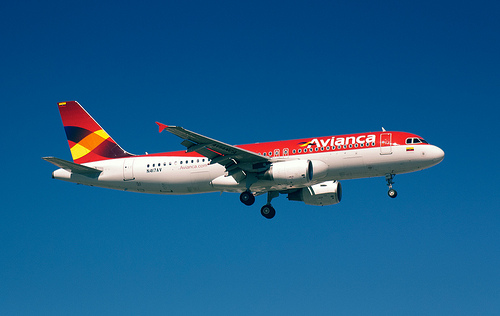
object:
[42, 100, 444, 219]
plane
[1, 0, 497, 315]
sky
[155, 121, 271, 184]
wing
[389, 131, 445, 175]
head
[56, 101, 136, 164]
tail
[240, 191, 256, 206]
wheels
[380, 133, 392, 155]
door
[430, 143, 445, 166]
nose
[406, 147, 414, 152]
flag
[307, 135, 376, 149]
lettering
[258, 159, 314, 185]
engine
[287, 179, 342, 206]
engine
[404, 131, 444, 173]
cock pit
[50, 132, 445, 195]
fusel lodge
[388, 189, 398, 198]
wheels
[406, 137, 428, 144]
front windows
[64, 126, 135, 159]
stripe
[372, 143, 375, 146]
windows